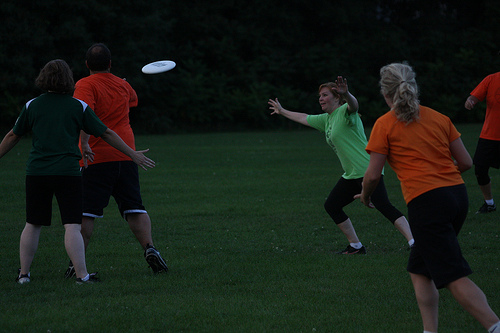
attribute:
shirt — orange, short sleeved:
[366, 103, 466, 203]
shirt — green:
[306, 101, 386, 179]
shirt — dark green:
[13, 91, 107, 177]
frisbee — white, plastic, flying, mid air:
[142, 59, 177, 74]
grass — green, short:
[0, 121, 498, 331]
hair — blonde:
[380, 59, 419, 126]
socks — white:
[350, 236, 415, 249]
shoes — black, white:
[65, 243, 169, 278]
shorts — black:
[407, 182, 474, 290]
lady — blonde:
[353, 60, 500, 332]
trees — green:
[0, 1, 498, 137]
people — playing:
[0, 41, 499, 331]